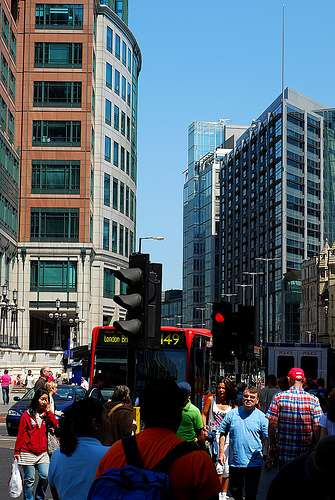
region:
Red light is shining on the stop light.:
[201, 310, 236, 334]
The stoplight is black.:
[208, 336, 233, 352]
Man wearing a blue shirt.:
[231, 430, 252, 450]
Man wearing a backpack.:
[101, 478, 133, 491]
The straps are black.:
[126, 442, 148, 461]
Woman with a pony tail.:
[52, 429, 73, 446]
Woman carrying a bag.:
[0, 461, 35, 479]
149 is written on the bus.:
[141, 327, 184, 344]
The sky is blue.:
[164, 44, 191, 50]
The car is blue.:
[53, 401, 75, 414]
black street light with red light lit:
[201, 277, 279, 372]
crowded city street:
[16, 263, 333, 494]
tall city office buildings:
[174, 93, 328, 329]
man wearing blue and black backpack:
[89, 381, 216, 497]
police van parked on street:
[259, 329, 332, 390]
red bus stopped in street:
[78, 307, 231, 437]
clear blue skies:
[168, 11, 257, 103]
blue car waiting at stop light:
[7, 370, 96, 434]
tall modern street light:
[135, 228, 170, 255]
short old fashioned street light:
[50, 293, 72, 354]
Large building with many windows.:
[32, 18, 129, 370]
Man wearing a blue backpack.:
[94, 400, 203, 498]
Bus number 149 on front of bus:
[149, 322, 207, 352]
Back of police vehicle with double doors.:
[255, 336, 333, 408]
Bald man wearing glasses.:
[32, 362, 58, 384]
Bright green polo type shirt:
[173, 399, 211, 438]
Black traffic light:
[104, 247, 162, 368]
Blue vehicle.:
[4, 382, 86, 438]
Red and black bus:
[79, 317, 212, 418]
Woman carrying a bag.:
[8, 384, 56, 498]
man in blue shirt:
[218, 385, 269, 498]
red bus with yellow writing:
[89, 323, 262, 408]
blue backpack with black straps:
[86, 432, 200, 499]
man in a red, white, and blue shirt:
[265, 366, 323, 468]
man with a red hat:
[268, 366, 324, 469]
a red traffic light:
[210, 300, 233, 359]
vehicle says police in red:
[262, 340, 332, 387]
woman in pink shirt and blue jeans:
[0, 368, 12, 404]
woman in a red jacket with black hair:
[12, 387, 58, 497]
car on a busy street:
[5, 382, 89, 433]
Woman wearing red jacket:
[4, 382, 75, 496]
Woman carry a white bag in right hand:
[6, 387, 64, 498]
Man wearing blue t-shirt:
[214, 375, 277, 495]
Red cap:
[281, 356, 317, 382]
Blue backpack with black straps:
[85, 429, 204, 498]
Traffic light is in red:
[205, 284, 239, 364]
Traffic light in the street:
[99, 247, 169, 375]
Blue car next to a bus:
[0, 375, 92, 434]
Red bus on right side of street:
[78, 317, 270, 416]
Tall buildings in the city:
[0, 0, 333, 333]